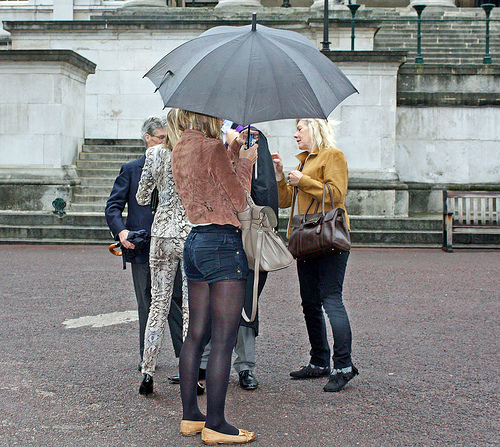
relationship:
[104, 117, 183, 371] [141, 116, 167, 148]
man has grey hair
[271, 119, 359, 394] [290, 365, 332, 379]
woman has a right foot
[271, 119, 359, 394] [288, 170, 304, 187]
woman has a left hand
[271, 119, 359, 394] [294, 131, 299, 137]
woman has a nose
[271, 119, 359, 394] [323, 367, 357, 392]
woman has a left foot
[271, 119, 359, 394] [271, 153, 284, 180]
woman has a right hand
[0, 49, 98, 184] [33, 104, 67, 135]
wall has a brick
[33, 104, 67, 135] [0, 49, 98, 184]
brick part of wall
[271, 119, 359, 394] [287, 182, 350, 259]
woman holding purse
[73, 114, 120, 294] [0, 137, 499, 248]
part of a outdoor stairway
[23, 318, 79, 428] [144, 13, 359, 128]
part of an part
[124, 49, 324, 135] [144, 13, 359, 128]
part of part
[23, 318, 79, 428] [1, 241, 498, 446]
part of ground